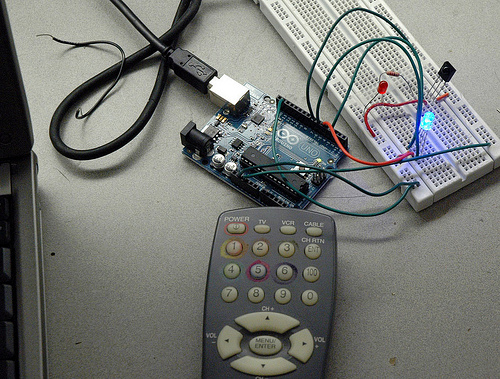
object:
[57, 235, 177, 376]
floor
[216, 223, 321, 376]
keyboard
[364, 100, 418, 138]
cable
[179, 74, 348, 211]
microcontroller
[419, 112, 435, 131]
led light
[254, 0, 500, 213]
circuit board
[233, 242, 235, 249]
number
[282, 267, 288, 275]
number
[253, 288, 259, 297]
number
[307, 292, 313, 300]
number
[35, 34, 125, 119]
cord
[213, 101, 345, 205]
electronic part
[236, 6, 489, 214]
wire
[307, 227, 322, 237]
button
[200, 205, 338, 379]
remote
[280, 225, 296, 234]
button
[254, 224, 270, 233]
button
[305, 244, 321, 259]
button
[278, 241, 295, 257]
button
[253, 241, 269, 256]
button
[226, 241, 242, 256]
button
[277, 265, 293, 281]
button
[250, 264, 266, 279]
button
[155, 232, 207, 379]
surface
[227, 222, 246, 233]
power button